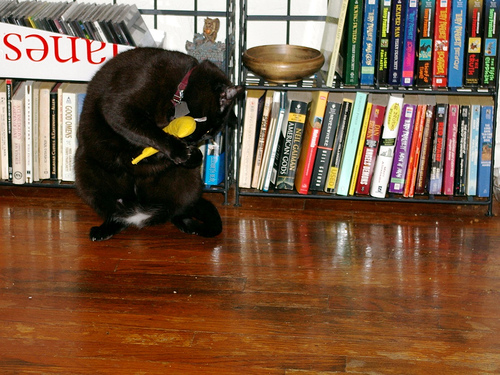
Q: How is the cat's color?
A: Black and white.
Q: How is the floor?
A: Wooden.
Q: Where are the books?
A: On shelf.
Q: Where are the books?
A: On bookcase.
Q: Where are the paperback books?
A: In a row.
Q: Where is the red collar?
A: On cat.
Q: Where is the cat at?
A: In front of books.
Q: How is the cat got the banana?
A: With paws.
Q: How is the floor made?
A: Wood.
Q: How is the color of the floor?
A: Brown.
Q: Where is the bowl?
A: By books.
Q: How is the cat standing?
A: On back legs.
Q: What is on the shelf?
A: Books.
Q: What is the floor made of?
A: Wood.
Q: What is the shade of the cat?
A: Black.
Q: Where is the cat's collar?
A: Neck.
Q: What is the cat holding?
A: Banana.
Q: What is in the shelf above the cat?
A: CDs.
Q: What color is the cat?
A: Black.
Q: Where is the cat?
A: In a room.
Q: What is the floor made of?
A: Wood.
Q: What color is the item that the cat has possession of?
A: Yellow.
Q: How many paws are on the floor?
A: Two.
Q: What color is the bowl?
A: Brown.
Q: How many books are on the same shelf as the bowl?
A: Eleven.